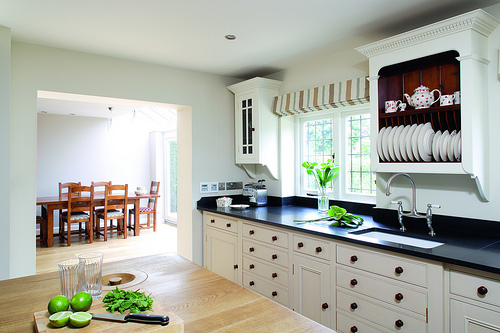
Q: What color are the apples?
A: Green.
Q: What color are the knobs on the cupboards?
A: Black.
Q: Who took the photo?
A: The photographer.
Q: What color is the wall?
A: White.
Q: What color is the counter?
A: Black.